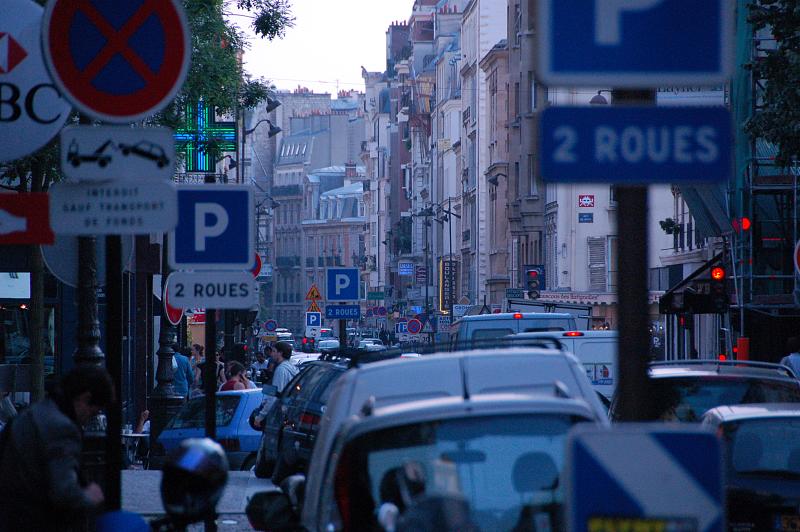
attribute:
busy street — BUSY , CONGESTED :
[250, 160, 786, 529]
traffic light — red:
[701, 202, 755, 300]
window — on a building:
[586, 238, 605, 259]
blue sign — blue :
[514, 2, 754, 208]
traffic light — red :
[679, 204, 760, 374]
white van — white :
[309, 337, 611, 527]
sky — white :
[202, 0, 405, 90]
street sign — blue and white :
[163, 180, 257, 431]